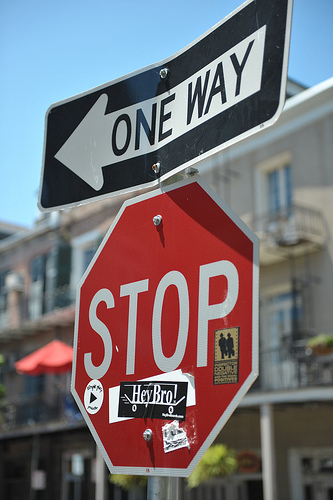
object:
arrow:
[52, 22, 267, 194]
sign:
[35, 0, 293, 211]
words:
[54, 21, 266, 193]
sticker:
[112, 377, 193, 417]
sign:
[69, 174, 259, 476]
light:
[132, 222, 146, 243]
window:
[262, 164, 291, 215]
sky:
[162, 23, 205, 35]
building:
[0, 74, 332, 499]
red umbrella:
[15, 337, 88, 373]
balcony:
[43, 402, 82, 429]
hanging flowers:
[183, 443, 241, 491]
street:
[280, 490, 288, 498]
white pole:
[258, 402, 281, 498]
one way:
[37, 0, 294, 210]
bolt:
[146, 210, 188, 231]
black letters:
[227, 42, 252, 98]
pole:
[145, 475, 179, 500]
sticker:
[81, 375, 105, 418]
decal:
[162, 432, 218, 457]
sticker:
[212, 326, 241, 385]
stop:
[81, 259, 238, 381]